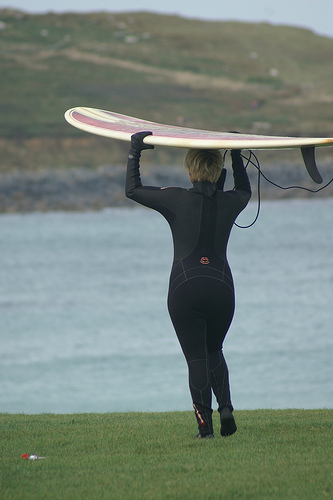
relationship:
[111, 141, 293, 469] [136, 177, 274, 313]
lady in suit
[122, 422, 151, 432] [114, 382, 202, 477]
grass on ground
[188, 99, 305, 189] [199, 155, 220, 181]
surfboard on head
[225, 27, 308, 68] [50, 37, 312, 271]
hill in background